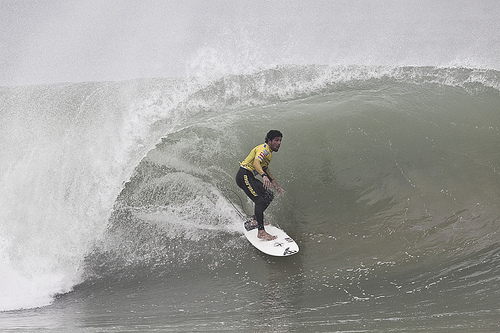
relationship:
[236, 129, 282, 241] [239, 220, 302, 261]
man on surfboard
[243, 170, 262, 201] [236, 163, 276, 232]
lettering on pants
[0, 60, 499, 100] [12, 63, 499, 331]
edge of ocean wave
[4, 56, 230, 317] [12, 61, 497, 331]
foam in water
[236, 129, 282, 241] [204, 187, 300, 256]
man on surfboard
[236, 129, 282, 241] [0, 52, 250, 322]
man in wave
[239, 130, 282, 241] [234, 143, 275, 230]
man wears body suit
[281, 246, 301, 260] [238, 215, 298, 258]
nose of surfboard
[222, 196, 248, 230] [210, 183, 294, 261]
string on surfboard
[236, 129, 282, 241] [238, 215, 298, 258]
man on surfboard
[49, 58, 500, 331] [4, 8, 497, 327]
ocean wave in ocean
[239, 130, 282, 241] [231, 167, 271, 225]
man wearing pants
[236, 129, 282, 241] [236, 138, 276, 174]
man wearing shirt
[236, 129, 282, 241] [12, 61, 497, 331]
man on water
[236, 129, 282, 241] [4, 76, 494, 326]
man surfing ocean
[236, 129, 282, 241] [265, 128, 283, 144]
man has hair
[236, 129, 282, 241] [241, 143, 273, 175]
man wearing shirt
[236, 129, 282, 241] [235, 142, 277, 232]
man wearing body suit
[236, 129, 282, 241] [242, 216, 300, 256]
man tethered to board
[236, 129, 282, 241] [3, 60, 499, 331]
man in wave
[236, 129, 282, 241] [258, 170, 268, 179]
man wearing watch